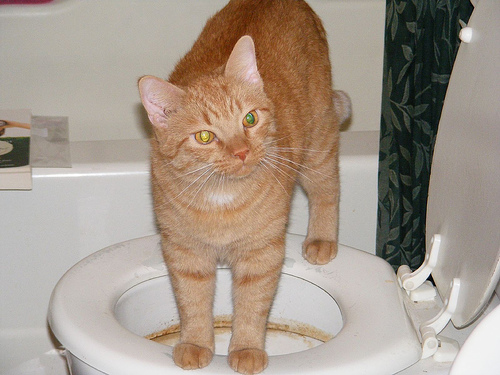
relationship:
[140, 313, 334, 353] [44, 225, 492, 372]
ring in toilet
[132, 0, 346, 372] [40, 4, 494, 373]
cat standing on toilet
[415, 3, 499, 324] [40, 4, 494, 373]
lid of toilet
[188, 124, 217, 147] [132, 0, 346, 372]
eye of cat